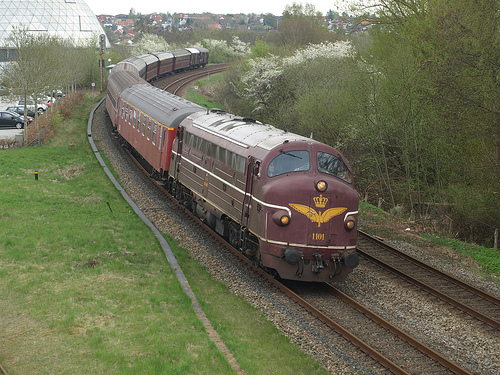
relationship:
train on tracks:
[100, 29, 368, 287] [344, 253, 483, 363]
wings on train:
[294, 191, 344, 234] [107, 35, 373, 312]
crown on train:
[282, 190, 352, 239] [77, 44, 369, 291]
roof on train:
[186, 46, 200, 56] [100, 29, 368, 287]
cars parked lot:
[4, 105, 39, 119] [6, 75, 60, 147]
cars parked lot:
[3, 83, 58, 135] [4, 87, 53, 129]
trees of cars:
[185, 13, 482, 200] [0, 76, 64, 133]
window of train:
[270, 140, 348, 182] [100, 29, 368, 287]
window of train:
[316, 151, 352, 184] [100, 29, 368, 287]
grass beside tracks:
[187, 229, 325, 373] [279, 202, 498, 373]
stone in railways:
[373, 265, 472, 351] [264, 222, 497, 373]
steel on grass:
[71, 69, 249, 373] [0, 102, 131, 352]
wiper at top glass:
[274, 138, 311, 166] [260, 138, 311, 185]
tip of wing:
[283, 196, 300, 214] [280, 191, 312, 220]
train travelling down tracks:
[105, 45, 361, 283] [279, 202, 498, 373]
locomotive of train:
[166, 93, 395, 294] [69, 25, 395, 305]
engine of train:
[147, 86, 385, 304] [76, 14, 426, 319]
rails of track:
[272, 273, 470, 373] [307, 220, 492, 367]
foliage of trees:
[337, 3, 496, 192] [254, 43, 495, 250]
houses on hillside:
[97, 6, 232, 52] [93, 9, 384, 64]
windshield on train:
[258, 141, 356, 188] [85, 14, 405, 307]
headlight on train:
[336, 213, 361, 232] [105, 45, 361, 283]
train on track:
[105, 45, 361, 283] [252, 191, 493, 373]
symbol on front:
[279, 196, 359, 231] [263, 173, 366, 274]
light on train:
[275, 209, 294, 227] [160, 93, 388, 304]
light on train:
[312, 173, 332, 195] [147, 90, 391, 292]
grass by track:
[3, 119, 133, 372] [126, 101, 497, 373]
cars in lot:
[2, 72, 78, 147] [0, 53, 90, 133]